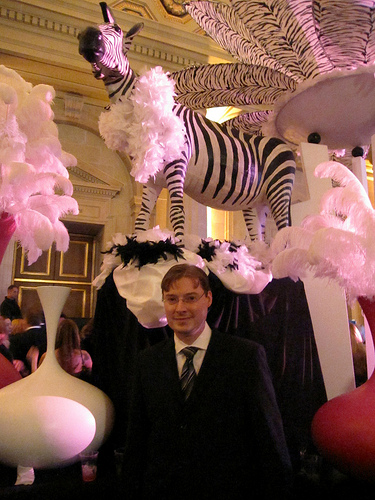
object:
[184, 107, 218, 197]
stripes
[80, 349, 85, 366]
straps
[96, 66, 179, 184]
boa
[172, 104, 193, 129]
stripe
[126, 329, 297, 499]
suit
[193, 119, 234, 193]
white stripes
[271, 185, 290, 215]
stripes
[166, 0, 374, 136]
feathers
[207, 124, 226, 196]
stripes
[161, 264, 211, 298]
hair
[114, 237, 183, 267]
feathers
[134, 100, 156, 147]
feathers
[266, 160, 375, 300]
feathers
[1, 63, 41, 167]
feathers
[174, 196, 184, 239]
stripes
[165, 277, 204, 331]
face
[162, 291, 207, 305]
glasses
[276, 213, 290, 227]
stripes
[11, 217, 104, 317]
doorway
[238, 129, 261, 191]
stripes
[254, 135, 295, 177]
stripes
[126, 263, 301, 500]
man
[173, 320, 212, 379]
shirt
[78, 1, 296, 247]
zebra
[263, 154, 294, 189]
stripes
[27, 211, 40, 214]
feather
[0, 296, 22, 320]
sweater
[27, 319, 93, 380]
woman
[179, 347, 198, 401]
tie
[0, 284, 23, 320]
person